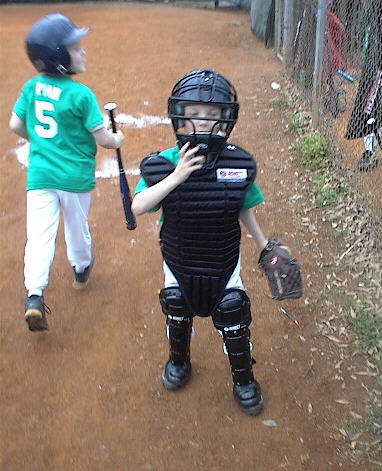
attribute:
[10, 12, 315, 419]
boys — playing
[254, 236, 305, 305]
catchers mitt — gray 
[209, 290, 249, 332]
knee pad — Black 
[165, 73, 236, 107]
helmet — Black 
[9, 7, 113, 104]
helmet — black 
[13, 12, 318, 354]
kids — playing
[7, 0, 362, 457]
field — baseball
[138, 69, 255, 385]
gear — black